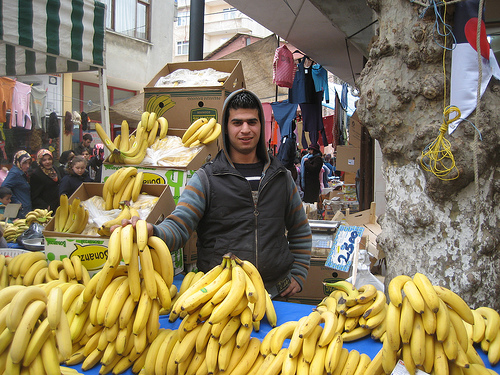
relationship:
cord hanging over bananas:
[417, 0, 466, 182] [388, 264, 498, 373]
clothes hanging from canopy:
[271, 38, 300, 90] [222, 0, 382, 87]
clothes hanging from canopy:
[270, 55, 310, 139] [222, 0, 382, 87]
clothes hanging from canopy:
[309, 60, 333, 106] [222, 0, 382, 87]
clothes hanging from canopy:
[330, 81, 355, 151] [222, 0, 382, 87]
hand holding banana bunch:
[138, 218, 159, 237] [104, 218, 181, 305]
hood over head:
[222, 89, 271, 171] [226, 90, 262, 150]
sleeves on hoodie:
[153, 164, 210, 251] [149, 88, 312, 293]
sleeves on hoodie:
[283, 164, 313, 286] [149, 88, 312, 293]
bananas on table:
[0, 215, 499, 373] [63, 275, 498, 373]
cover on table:
[59, 295, 499, 373] [0, 243, 498, 370]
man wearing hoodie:
[110, 89, 312, 302] [152, 87, 313, 294]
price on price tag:
[336, 229, 360, 264] [324, 225, 365, 272]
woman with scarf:
[27, 147, 66, 210] [32, 148, 51, 168]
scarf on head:
[32, 148, 51, 168] [32, 145, 57, 170]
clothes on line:
[2, 79, 51, 134] [32, 86, 102, 105]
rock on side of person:
[350, 0, 484, 306] [135, 79, 316, 302]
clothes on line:
[273, 44, 297, 88] [279, 1, 310, 47]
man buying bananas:
[112, 84, 321, 309] [106, 219, 175, 306]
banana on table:
[172, 249, 277, 352] [2, 282, 482, 372]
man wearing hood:
[112, 84, 321, 309] [218, 87, 269, 167]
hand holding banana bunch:
[110, 215, 153, 237] [102, 218, 152, 270]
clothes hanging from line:
[1, 77, 47, 133] [42, 91, 129, 114]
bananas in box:
[92, 110, 169, 168] [102, 128, 221, 169]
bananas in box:
[176, 116, 220, 152] [102, 128, 221, 169]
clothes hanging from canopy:
[273, 44, 297, 88] [219, 0, 375, 87]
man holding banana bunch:
[112, 84, 321, 309] [102, 218, 152, 270]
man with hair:
[112, 84, 321, 309] [229, 92, 264, 112]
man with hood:
[110, 89, 312, 302] [215, 89, 268, 160]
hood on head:
[215, 89, 268, 160] [224, 90, 263, 159]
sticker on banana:
[200, 284, 212, 296] [178, 256, 230, 317]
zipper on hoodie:
[247, 204, 266, 217] [149, 88, 312, 293]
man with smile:
[112, 84, 321, 309] [232, 133, 255, 146]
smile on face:
[232, 133, 255, 146] [223, 111, 258, 153]